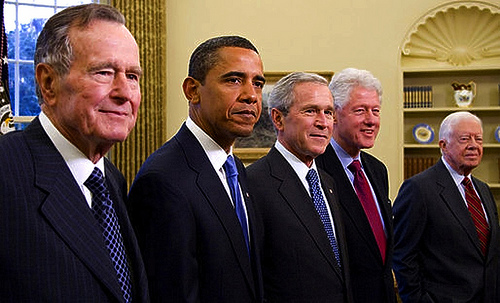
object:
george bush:
[0, 2, 152, 302]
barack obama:
[126, 77, 278, 303]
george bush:
[244, 71, 352, 302]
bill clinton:
[315, 67, 395, 302]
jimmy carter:
[389, 110, 500, 302]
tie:
[84, 168, 131, 303]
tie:
[348, 161, 386, 267]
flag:
[0, 0, 17, 135]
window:
[4, 0, 101, 129]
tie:
[222, 157, 250, 259]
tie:
[462, 178, 490, 259]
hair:
[438, 110, 485, 158]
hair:
[328, 67, 384, 109]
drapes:
[93, 1, 166, 195]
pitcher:
[449, 81, 478, 108]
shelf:
[403, 105, 500, 112]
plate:
[412, 122, 435, 144]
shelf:
[404, 143, 500, 148]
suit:
[0, 111, 150, 301]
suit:
[317, 142, 394, 302]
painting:
[233, 70, 335, 161]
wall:
[166, 0, 499, 277]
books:
[403, 86, 408, 109]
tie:
[306, 169, 341, 267]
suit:
[244, 142, 353, 302]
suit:
[126, 121, 265, 302]